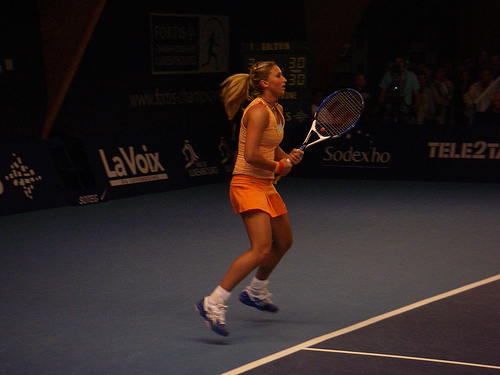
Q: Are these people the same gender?
A: No, they are both male and female.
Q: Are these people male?
A: No, they are both male and female.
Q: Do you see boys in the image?
A: No, there are no boys.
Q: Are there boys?
A: No, there are no boys.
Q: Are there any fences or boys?
A: No, there are no boys or fences.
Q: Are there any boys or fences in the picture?
A: No, there are no boys or fences.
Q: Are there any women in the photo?
A: Yes, there is a woman.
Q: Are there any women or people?
A: Yes, there is a woman.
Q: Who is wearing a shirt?
A: The woman is wearing a shirt.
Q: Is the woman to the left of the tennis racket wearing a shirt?
A: Yes, the woman is wearing a shirt.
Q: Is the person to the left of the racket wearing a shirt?
A: Yes, the woman is wearing a shirt.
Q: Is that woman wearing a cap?
A: No, the woman is wearing a shirt.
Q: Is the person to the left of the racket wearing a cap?
A: No, the woman is wearing a shirt.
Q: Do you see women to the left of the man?
A: Yes, there is a woman to the left of the man.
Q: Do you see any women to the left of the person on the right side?
A: Yes, there is a woman to the left of the man.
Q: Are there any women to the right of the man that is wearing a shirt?
A: No, the woman is to the left of the man.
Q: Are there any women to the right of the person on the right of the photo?
A: No, the woman is to the left of the man.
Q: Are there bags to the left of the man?
A: No, there is a woman to the left of the man.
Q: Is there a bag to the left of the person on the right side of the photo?
A: No, there is a woman to the left of the man.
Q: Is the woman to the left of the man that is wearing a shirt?
A: Yes, the woman is to the left of the man.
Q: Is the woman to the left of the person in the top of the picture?
A: Yes, the woman is to the left of the man.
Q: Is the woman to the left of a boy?
A: No, the woman is to the left of the man.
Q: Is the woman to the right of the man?
A: No, the woman is to the left of the man.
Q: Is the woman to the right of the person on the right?
A: No, the woman is to the left of the man.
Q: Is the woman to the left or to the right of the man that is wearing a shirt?
A: The woman is to the left of the man.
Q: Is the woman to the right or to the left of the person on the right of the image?
A: The woman is to the left of the man.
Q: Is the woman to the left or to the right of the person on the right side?
A: The woman is to the left of the man.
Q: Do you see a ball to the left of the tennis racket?
A: No, there is a woman to the left of the tennis racket.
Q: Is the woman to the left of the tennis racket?
A: Yes, the woman is to the left of the tennis racket.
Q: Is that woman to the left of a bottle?
A: No, the woman is to the left of the tennis racket.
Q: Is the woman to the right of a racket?
A: No, the woman is to the left of a racket.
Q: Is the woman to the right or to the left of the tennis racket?
A: The woman is to the left of the tennis racket.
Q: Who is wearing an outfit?
A: The woman is wearing an outfit.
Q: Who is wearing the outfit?
A: The woman is wearing an outfit.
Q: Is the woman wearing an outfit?
A: Yes, the woman is wearing an outfit.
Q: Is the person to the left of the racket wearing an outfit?
A: Yes, the woman is wearing an outfit.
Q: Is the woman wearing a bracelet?
A: No, the woman is wearing an outfit.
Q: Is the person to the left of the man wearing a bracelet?
A: No, the woman is wearing an outfit.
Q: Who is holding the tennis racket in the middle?
A: The woman is holding the tennis racket.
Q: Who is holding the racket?
A: The woman is holding the tennis racket.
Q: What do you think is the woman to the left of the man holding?
A: The woman is holding the racket.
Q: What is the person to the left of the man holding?
A: The woman is holding the racket.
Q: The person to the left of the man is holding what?
A: The woman is holding the racket.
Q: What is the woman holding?
A: The woman is holding the racket.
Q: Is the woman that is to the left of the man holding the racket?
A: Yes, the woman is holding the racket.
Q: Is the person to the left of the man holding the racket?
A: Yes, the woman is holding the racket.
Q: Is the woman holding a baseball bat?
A: No, the woman is holding the racket.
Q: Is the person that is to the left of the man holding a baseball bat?
A: No, the woman is holding the racket.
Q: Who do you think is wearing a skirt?
A: The woman is wearing a skirt.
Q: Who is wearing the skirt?
A: The woman is wearing a skirt.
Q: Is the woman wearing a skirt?
A: Yes, the woman is wearing a skirt.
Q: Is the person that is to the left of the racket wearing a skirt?
A: Yes, the woman is wearing a skirt.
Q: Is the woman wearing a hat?
A: No, the woman is wearing a skirt.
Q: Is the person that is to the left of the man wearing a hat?
A: No, the woman is wearing a skirt.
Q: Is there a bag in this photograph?
A: No, there are no bags.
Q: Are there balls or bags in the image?
A: No, there are no bags or balls.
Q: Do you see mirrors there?
A: No, there are no mirrors.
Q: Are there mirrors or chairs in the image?
A: No, there are no mirrors or chairs.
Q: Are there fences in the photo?
A: No, there are no fences.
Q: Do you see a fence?
A: No, there are no fences.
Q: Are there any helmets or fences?
A: No, there are no fences or helmets.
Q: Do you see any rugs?
A: No, there are no rugs.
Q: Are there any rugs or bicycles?
A: No, there are no rugs or bicycles.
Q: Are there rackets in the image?
A: Yes, there is a racket.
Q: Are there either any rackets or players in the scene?
A: Yes, there is a racket.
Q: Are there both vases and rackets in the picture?
A: No, there is a racket but no vases.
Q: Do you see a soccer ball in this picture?
A: No, there are no soccer balls.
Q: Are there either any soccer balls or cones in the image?
A: No, there are no soccer balls or cones.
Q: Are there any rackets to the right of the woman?
A: Yes, there is a racket to the right of the woman.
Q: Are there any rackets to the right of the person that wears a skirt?
A: Yes, there is a racket to the right of the woman.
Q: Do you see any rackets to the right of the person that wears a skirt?
A: Yes, there is a racket to the right of the woman.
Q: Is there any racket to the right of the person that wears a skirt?
A: Yes, there is a racket to the right of the woman.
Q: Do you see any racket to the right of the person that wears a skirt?
A: Yes, there is a racket to the right of the woman.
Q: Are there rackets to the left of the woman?
A: No, the racket is to the right of the woman.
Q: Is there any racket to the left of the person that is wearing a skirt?
A: No, the racket is to the right of the woman.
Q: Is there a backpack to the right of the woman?
A: No, there is a racket to the right of the woman.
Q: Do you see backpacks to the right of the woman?
A: No, there is a racket to the right of the woman.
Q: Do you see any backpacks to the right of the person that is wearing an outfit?
A: No, there is a racket to the right of the woman.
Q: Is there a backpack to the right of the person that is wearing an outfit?
A: No, there is a racket to the right of the woman.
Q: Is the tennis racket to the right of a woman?
A: Yes, the tennis racket is to the right of a woman.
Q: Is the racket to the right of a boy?
A: No, the racket is to the right of a woman.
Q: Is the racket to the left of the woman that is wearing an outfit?
A: No, the racket is to the right of the woman.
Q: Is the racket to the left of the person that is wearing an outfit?
A: No, the racket is to the right of the woman.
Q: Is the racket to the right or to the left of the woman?
A: The racket is to the right of the woman.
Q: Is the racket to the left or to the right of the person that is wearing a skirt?
A: The racket is to the right of the woman.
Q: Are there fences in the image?
A: No, there are no fences.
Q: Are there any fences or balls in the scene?
A: No, there are no fences or balls.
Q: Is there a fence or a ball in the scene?
A: No, there are no fences or balls.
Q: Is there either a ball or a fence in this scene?
A: No, there are no fences or balls.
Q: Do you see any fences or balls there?
A: No, there are no fences or balls.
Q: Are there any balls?
A: No, there are no balls.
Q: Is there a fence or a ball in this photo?
A: No, there are no balls or fences.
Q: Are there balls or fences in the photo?
A: No, there are no balls or fences.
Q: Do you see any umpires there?
A: No, there are no umpires.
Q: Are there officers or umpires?
A: No, there are no umpires or officers.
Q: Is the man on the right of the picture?
A: Yes, the man is on the right of the image.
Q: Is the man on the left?
A: No, the man is on the right of the image.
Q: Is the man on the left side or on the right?
A: The man is on the right of the image.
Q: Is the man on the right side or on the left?
A: The man is on the right of the image.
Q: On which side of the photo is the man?
A: The man is on the right of the image.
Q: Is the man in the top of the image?
A: Yes, the man is in the top of the image.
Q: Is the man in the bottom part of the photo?
A: No, the man is in the top of the image.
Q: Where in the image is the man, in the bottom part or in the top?
A: The man is in the top of the image.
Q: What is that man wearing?
A: The man is wearing a shirt.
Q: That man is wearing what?
A: The man is wearing a shirt.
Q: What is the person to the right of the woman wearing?
A: The man is wearing a shirt.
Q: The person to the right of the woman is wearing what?
A: The man is wearing a shirt.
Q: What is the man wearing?
A: The man is wearing a shirt.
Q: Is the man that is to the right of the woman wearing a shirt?
A: Yes, the man is wearing a shirt.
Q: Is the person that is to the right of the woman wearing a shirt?
A: Yes, the man is wearing a shirt.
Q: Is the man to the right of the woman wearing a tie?
A: No, the man is wearing a shirt.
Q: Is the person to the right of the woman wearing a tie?
A: No, the man is wearing a shirt.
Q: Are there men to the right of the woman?
A: Yes, there is a man to the right of the woman.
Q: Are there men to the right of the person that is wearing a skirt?
A: Yes, there is a man to the right of the woman.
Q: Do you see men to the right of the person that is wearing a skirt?
A: Yes, there is a man to the right of the woman.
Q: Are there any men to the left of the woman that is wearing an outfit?
A: No, the man is to the right of the woman.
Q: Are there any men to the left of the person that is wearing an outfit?
A: No, the man is to the right of the woman.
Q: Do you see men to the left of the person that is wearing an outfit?
A: No, the man is to the right of the woman.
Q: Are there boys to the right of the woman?
A: No, there is a man to the right of the woman.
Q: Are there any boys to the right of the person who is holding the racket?
A: No, there is a man to the right of the woman.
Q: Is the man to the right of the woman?
A: Yes, the man is to the right of the woman.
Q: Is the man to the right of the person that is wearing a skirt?
A: Yes, the man is to the right of the woman.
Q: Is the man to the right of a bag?
A: No, the man is to the right of the woman.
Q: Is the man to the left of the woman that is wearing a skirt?
A: No, the man is to the right of the woman.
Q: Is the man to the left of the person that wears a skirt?
A: No, the man is to the right of the woman.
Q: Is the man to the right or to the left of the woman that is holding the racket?
A: The man is to the right of the woman.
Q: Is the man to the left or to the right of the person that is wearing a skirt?
A: The man is to the right of the woman.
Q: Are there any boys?
A: No, there are no boys.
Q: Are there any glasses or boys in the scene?
A: No, there are no boys or glasses.